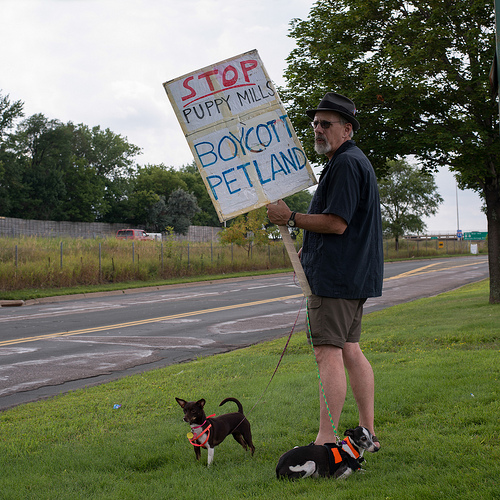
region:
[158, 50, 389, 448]
man holding a sign on the side of the road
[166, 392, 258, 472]
brown and white chihuahua standing in the grass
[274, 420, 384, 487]
dog laying in the grass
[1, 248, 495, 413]
two lane road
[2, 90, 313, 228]
trees in the backkground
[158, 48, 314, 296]
homemade sign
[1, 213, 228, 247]
fence near the wooded area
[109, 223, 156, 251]
old red pick up truck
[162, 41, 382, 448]
man protesting on the side of the road holding a sign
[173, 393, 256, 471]
chihuahua looking alert at something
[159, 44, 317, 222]
Sign protesting puppy mills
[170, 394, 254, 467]
black and white standing puppy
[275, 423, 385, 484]
black and white puppy lying down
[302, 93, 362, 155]
protesting man's head and hat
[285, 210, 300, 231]
protesting man's wristwatch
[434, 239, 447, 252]
roadsign in the distance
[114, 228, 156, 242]
red truck with cover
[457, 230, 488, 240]
green road sign in the distance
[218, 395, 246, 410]
standing puppy's tail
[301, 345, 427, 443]
protesting man's bare legs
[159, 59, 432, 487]
man holding with dogs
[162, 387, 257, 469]
dog with red leash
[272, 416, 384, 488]
dog with orange leash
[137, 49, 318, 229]
sign that says stop puppy mills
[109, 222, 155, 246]
red vehicle in the field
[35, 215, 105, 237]
wooden fence in the field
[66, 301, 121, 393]
yellow strip on the road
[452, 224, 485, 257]
green sign in the background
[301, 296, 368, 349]
brown shorts man is wearing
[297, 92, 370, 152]
man wearing glasses and hat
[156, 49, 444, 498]
A man is boycotting standing on grass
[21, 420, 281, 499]
The grass is cut short and green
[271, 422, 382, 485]
A small dog sitting down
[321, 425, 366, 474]
The dog has an orange harness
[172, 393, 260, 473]
A small dog standing up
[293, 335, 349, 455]
The leg of the man standing up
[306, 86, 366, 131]
The man has on a brown hat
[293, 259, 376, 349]
The man has on brown shorts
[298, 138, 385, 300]
The man has on a black shirt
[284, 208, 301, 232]
The man has on a watch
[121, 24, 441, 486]
Lone protestor with sign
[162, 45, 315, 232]
Protestor's sign indicating his cause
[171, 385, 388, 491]
Two small doggies by his side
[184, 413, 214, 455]
Wearing a brightly colored harness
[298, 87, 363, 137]
Wearing an old style hat and sunglasses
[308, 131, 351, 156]
Gentleman has a lot of facial hair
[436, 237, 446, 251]
Street sign in the distance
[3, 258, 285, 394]
Street is in poor condition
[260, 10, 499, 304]
Big tree in the background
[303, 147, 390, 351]
Blue short sleeve shirt and brown shorts